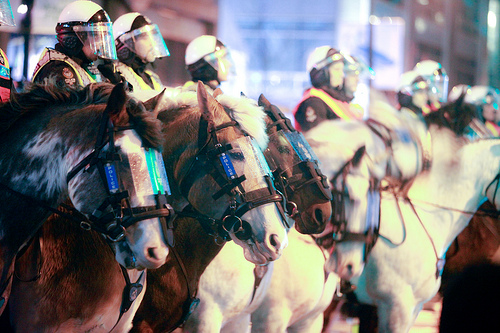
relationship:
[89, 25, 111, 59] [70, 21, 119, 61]
reflection on face mask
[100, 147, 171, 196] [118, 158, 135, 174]
shield in front of eye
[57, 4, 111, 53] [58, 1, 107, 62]
helmet on head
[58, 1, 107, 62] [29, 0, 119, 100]
head of people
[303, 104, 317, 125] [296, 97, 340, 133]
logo on jacket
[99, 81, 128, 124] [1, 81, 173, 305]
right ear of horse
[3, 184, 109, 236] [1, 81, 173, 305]
reigns are on horse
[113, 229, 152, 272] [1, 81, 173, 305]
mouth of horse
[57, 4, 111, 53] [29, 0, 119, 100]
helmet on people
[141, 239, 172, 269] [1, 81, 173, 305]
nose of horse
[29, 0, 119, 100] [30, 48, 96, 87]
people wearing vest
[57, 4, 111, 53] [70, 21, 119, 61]
helmet has visor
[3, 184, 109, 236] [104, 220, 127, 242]
reigns are attached to bit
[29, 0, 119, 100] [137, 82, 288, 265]
people on horse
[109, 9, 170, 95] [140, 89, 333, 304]
policeman on horse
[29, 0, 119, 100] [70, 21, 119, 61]
people with face mask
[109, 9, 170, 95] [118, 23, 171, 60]
policeman with face mask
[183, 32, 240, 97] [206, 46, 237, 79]
policeman with face mask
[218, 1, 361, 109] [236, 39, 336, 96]
building has window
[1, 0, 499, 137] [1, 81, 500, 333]
people are on horses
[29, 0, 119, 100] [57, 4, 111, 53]
people wearing helmet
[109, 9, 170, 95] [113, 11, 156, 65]
policeman wearing helmet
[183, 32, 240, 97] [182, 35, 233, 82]
policeman wearing helmet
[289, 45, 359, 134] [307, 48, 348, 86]
policeman wearing helmet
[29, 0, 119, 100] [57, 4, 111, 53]
people with helmet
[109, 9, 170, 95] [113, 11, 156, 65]
policeman with helmet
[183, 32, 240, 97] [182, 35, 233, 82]
policeman with helmet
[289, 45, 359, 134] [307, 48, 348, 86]
policeman with helmet